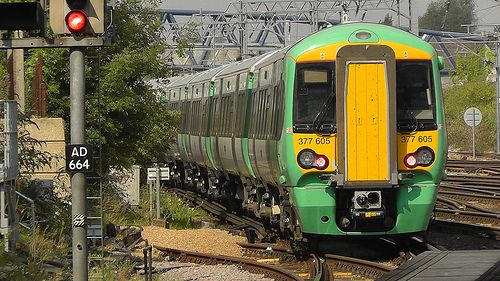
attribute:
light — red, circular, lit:
[65, 10, 86, 32]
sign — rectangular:
[146, 168, 169, 182]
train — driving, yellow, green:
[126, 23, 451, 234]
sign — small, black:
[63, 144, 89, 171]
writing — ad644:
[67, 146, 89, 171]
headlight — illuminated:
[315, 154, 325, 167]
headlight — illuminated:
[407, 156, 416, 167]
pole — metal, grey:
[67, 50, 89, 281]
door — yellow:
[348, 63, 390, 182]